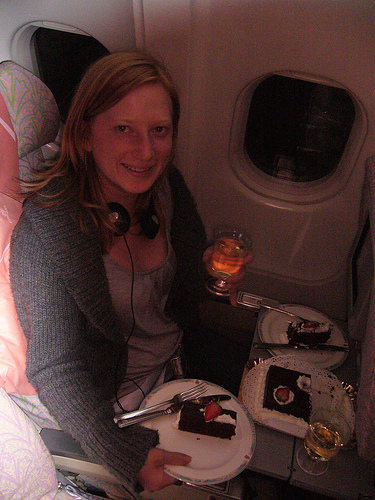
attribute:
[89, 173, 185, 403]
shirt — gray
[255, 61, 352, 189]
window — small, round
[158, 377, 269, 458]
cake — chocolate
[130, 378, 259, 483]
plate — white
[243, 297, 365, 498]
table — small, grey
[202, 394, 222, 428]
strawberry — topping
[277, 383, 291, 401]
strawberry — topping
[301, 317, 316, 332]
strawberry — topping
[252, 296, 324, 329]
knife — silver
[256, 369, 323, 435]
cake — black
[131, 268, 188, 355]
shirt — grey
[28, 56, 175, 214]
hair — dark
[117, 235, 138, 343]
wire — black